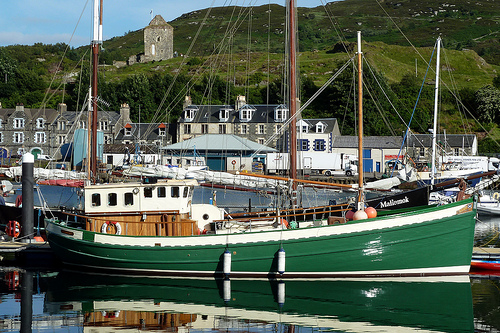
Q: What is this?
A: A harbour.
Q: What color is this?
A: Green.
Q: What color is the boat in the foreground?
A: Green.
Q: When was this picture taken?
A: Daytime.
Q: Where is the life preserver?
A: On cabin of closest boat.